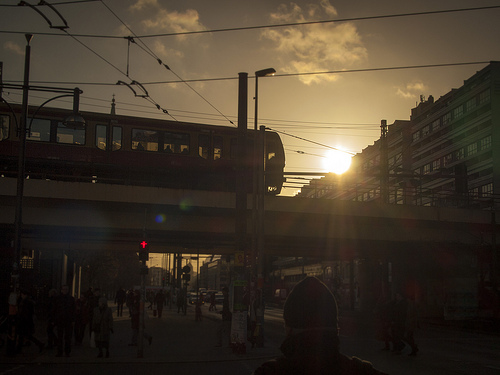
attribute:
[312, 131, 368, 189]
sun — glowing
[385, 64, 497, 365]
building — tall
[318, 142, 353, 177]
setting sun — in the evening sky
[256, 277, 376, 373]
back — of a person walking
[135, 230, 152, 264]
signal — on the road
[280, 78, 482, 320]
buildings — by the roadside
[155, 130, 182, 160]
window — glass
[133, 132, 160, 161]
window — glass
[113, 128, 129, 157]
window — glass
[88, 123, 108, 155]
window — glass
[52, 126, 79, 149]
window — glass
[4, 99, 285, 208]
window — glass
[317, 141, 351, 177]
sun — bright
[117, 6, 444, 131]
clouds — small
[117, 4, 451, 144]
clouds — small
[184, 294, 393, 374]
road — dark colored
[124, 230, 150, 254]
light — red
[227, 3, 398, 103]
clouds — thin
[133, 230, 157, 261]
cross — red